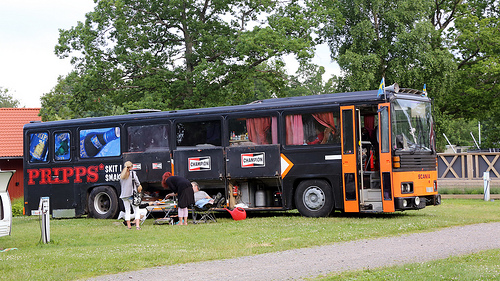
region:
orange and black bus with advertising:
[0, 96, 449, 222]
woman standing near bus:
[110, 156, 150, 226]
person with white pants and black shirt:
[157, 165, 198, 227]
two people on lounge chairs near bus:
[117, 183, 239, 220]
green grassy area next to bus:
[17, 208, 345, 260]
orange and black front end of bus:
[334, 78, 443, 215]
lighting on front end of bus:
[386, 174, 449, 219]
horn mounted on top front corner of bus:
[377, 79, 404, 108]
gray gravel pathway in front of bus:
[252, 222, 497, 269]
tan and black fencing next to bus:
[425, 145, 496, 196]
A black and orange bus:
[21, 83, 440, 223]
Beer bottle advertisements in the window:
[29, 128, 128, 160]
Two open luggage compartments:
[190, 183, 292, 216]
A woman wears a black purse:
[118, 162, 145, 229]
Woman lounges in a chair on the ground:
[191, 181, 236, 221]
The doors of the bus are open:
[336, 99, 399, 216]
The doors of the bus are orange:
[341, 98, 401, 219]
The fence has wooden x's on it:
[436, 152, 496, 189]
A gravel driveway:
[143, 211, 498, 278]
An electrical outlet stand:
[36, 193, 61, 241]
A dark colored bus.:
[23, 83, 439, 215]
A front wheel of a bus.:
[293, 179, 332, 216]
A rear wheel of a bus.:
[90, 185, 117, 218]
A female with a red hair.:
[160, 172, 195, 225]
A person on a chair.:
[192, 180, 224, 222]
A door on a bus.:
[341, 100, 396, 212]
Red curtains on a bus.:
[285, 111, 340, 143]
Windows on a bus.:
[26, 108, 338, 161]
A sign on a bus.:
[28, 163, 121, 185]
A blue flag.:
[376, 75, 387, 97]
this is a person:
[146, 158, 202, 234]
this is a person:
[92, 155, 145, 232]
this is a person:
[185, 176, 225, 224]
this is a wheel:
[293, 170, 335, 226]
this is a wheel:
[83, 183, 120, 226]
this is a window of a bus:
[283, 109, 340, 149]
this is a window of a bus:
[225, 111, 272, 145]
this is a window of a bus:
[173, 115, 226, 151]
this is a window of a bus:
[119, 126, 175, 153]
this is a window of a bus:
[71, 128, 128, 158]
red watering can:
[222, 205, 254, 223]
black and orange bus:
[20, 75, 442, 213]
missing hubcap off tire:
[97, 191, 111, 214]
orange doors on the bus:
[336, 99, 398, 217]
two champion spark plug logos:
[184, 146, 274, 177]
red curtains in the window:
[242, 111, 332, 151]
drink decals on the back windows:
[14, 123, 122, 165]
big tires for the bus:
[294, 180, 331, 216]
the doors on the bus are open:
[324, 94, 407, 216]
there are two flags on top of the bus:
[374, 69, 434, 107]